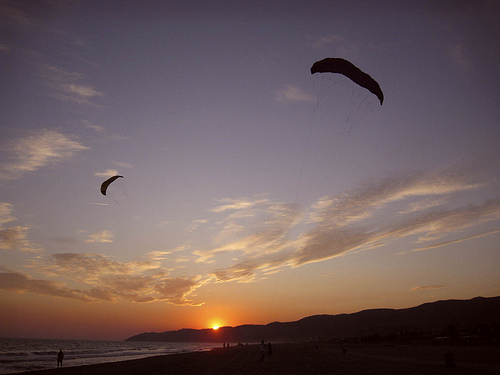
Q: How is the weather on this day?
A: It is cloudy.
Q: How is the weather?
A: It is cloudy.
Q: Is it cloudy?
A: Yes, it is cloudy.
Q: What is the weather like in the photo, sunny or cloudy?
A: It is cloudy.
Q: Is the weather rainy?
A: No, it is cloudy.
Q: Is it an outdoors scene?
A: Yes, it is outdoors.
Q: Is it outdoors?
A: Yes, it is outdoors.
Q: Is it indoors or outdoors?
A: It is outdoors.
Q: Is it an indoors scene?
A: No, it is outdoors.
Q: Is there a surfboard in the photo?
A: No, there are no surfboards.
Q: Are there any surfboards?
A: No, there are no surfboards.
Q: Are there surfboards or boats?
A: No, there are no surfboards or boats.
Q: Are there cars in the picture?
A: No, there are no cars.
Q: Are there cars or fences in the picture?
A: No, there are no cars or fences.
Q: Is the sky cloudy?
A: Yes, the sky is cloudy.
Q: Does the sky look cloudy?
A: Yes, the sky is cloudy.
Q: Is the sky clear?
A: No, the sky is cloudy.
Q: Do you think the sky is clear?
A: No, the sky is cloudy.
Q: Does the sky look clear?
A: No, the sky is cloudy.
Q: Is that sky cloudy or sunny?
A: The sky is cloudy.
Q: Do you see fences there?
A: No, there are no fences.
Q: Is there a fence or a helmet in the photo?
A: No, there are no fences or helmets.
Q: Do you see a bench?
A: No, there are no benches.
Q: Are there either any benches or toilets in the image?
A: No, there are no benches or toilets.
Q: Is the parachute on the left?
A: Yes, the parachute is on the left of the image.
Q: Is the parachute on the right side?
A: No, the parachute is on the left of the image.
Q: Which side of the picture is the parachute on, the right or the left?
A: The parachute is on the left of the image.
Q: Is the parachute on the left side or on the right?
A: The parachute is on the left of the image.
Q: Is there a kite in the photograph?
A: Yes, there is a kite.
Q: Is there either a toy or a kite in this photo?
A: Yes, there is a kite.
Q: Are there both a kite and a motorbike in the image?
A: No, there is a kite but no motorcycles.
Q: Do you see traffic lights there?
A: No, there are no traffic lights.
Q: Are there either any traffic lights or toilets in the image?
A: No, there are no traffic lights or toilets.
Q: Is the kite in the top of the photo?
A: Yes, the kite is in the top of the image.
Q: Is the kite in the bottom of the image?
A: No, the kite is in the top of the image.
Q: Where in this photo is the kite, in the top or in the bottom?
A: The kite is in the top of the image.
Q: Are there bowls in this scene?
A: No, there are no bowls.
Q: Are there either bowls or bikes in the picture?
A: No, there are no bowls or bikes.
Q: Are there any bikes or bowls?
A: No, there are no bowls or bikes.